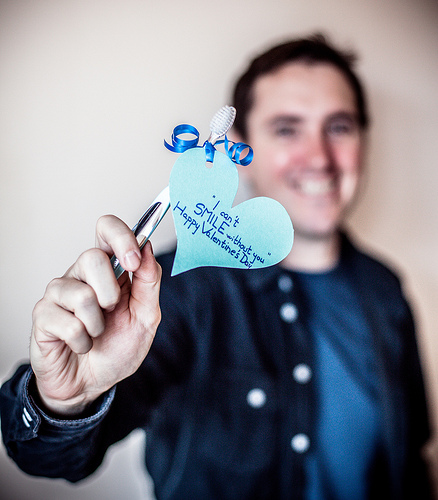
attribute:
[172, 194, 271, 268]
note — handwritten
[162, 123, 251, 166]
ribbon — blue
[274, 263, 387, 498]
shirt — light blue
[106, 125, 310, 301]
toothbrush — plastic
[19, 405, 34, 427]
buttons — white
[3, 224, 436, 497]
shirt — denim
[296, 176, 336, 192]
teeth — man's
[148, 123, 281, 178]
ribbon — blue, curled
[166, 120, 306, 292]
heart — blue, paper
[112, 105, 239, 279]
toothbrush — new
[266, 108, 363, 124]
eyebrows — brown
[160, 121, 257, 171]
ribbon — blue, curled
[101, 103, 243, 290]
toothbrush — new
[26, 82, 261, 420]
toothbrush — plastic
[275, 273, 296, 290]
button — white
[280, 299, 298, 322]
button — white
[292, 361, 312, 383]
button — white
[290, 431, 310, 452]
button — white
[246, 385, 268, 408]
button — white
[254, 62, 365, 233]
face — smiling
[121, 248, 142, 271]
fingernail — clean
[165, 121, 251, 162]
ribbon — blue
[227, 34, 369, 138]
hair — dark, brown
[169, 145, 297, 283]
paper — heart shaped